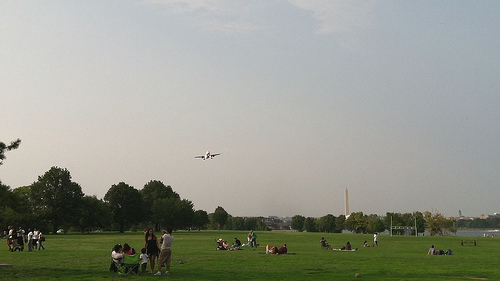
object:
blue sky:
[0, 0, 499, 217]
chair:
[119, 252, 141, 276]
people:
[153, 228, 173, 277]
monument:
[344, 187, 350, 220]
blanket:
[329, 247, 356, 252]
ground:
[0, 229, 499, 281]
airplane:
[192, 150, 222, 161]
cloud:
[0, 0, 499, 219]